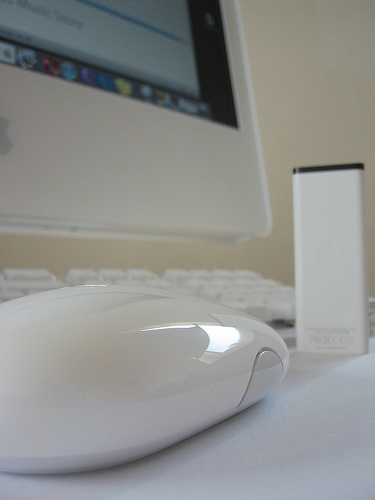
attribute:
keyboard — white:
[0, 259, 296, 323]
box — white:
[294, 165, 367, 356]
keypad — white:
[163, 263, 300, 324]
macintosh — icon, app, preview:
[299, 324, 359, 355]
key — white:
[214, 269, 237, 284]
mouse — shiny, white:
[0, 286, 291, 473]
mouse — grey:
[1, 272, 254, 486]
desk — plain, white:
[3, 308, 372, 498]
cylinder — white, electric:
[291, 164, 371, 362]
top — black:
[285, 153, 362, 175]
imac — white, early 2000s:
[2, 0, 307, 346]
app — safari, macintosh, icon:
[55, 56, 79, 83]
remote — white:
[294, 158, 366, 351]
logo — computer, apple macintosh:
[1, 120, 18, 149]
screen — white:
[3, 1, 253, 132]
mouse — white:
[16, 250, 312, 475]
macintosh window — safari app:
[2, 2, 243, 132]